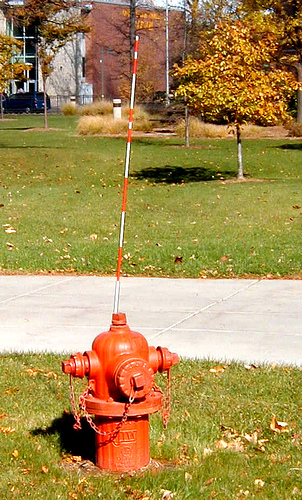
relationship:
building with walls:
[1, 1, 200, 113] [38, 1, 183, 99]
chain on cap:
[154, 367, 172, 425] [157, 346, 179, 374]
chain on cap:
[81, 404, 117, 440] [117, 358, 153, 398]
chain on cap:
[69, 373, 90, 429] [61, 351, 83, 378]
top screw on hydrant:
[112, 312, 125, 323] [60, 311, 181, 473]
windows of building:
[8, 12, 38, 92] [0, 0, 186, 106]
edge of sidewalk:
[2, 276, 300, 289] [1, 274, 300, 365]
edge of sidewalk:
[179, 349, 298, 367] [0, 267, 300, 370]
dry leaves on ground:
[174, 404, 300, 470] [1, 110, 300, 497]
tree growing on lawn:
[168, 22, 301, 179] [1, 114, 301, 275]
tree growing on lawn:
[0, 30, 24, 105] [1, 114, 301, 275]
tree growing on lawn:
[8, 0, 91, 128] [1, 114, 301, 275]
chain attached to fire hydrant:
[81, 380, 138, 438] [61, 308, 180, 471]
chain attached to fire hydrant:
[154, 367, 172, 431] [61, 308, 180, 471]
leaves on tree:
[203, 63, 277, 122] [168, 20, 301, 179]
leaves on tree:
[205, 18, 280, 74] [168, 20, 301, 179]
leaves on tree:
[168, 53, 230, 80] [168, 20, 301, 179]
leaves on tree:
[244, 67, 299, 122] [168, 20, 301, 179]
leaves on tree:
[171, 80, 253, 123] [168, 20, 301, 179]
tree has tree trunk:
[168, 20, 301, 179] [234, 139, 244, 179]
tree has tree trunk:
[161, 1, 205, 147] [183, 115, 189, 146]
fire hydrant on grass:
[61, 313, 179, 471] [0, 351, 300, 497]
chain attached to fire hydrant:
[69, 373, 90, 432] [61, 308, 180, 471]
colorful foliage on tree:
[168, 18, 299, 124] [168, 20, 301, 179]